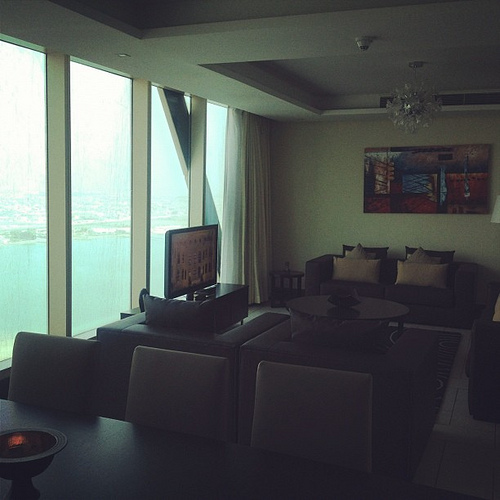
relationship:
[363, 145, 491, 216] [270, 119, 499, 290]
picture hanging on wall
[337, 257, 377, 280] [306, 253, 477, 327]
pillow on top of couch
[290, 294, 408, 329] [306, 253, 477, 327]
table near couch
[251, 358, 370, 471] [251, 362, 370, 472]
chair has back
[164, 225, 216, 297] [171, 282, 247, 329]
screen on top of table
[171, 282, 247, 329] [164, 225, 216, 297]
table has screen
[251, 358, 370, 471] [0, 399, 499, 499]
chair at table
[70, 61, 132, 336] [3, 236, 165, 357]
window overlooks water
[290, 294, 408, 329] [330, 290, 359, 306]
table has bowl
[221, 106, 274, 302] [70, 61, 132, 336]
curtain next to window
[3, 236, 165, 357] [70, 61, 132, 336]
water behind window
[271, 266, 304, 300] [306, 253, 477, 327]
table next to couch